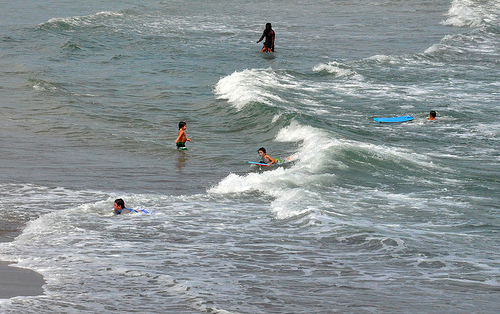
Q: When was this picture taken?
A: Daytime.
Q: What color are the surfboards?
A: Blue.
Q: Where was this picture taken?
A: An ocean.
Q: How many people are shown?
A: Five.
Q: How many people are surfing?
A: Two.